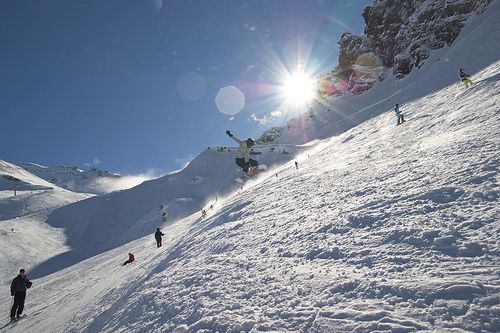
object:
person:
[458, 68, 477, 92]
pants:
[462, 79, 473, 90]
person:
[392, 103, 407, 126]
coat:
[394, 108, 404, 117]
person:
[224, 129, 268, 187]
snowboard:
[235, 162, 267, 187]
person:
[120, 250, 136, 268]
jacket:
[128, 252, 137, 263]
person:
[152, 227, 167, 248]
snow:
[0, 158, 498, 332]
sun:
[251, 44, 341, 129]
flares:
[257, 37, 323, 69]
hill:
[0, 158, 99, 224]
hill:
[30, 162, 145, 197]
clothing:
[154, 231, 164, 248]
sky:
[1, 1, 376, 177]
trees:
[318, 2, 492, 99]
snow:
[402, 9, 421, 22]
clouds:
[84, 154, 106, 169]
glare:
[174, 68, 255, 124]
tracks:
[268, 186, 499, 332]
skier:
[1, 266, 37, 331]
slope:
[3, 207, 256, 331]